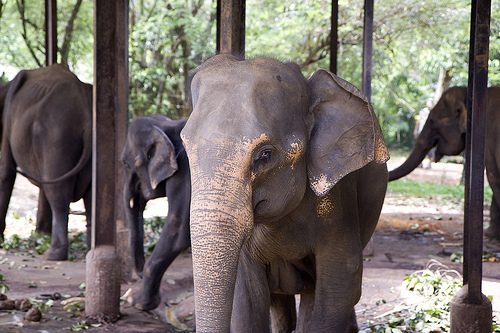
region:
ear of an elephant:
[338, 109, 399, 173]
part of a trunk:
[201, 272, 234, 312]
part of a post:
[448, 215, 488, 297]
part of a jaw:
[261, 176, 300, 231]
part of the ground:
[41, 278, 81, 313]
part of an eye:
[252, 147, 284, 154]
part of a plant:
[410, 269, 442, 312]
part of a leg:
[315, 242, 352, 309]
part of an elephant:
[119, 177, 322, 242]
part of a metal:
[459, 260, 486, 310]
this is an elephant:
[178, 48, 375, 301]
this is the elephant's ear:
[309, 72, 386, 188]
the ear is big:
[318, 63, 386, 192]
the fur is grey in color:
[227, 71, 289, 111]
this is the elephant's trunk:
[190, 165, 252, 323]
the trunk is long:
[191, 239, 232, 326]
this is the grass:
[397, 249, 444, 330]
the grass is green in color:
[411, 265, 448, 321]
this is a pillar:
[462, 12, 485, 182]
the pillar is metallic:
[463, 178, 478, 243]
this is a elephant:
[186, 32, 368, 332]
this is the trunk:
[188, 226, 231, 331]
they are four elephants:
[6, 64, 498, 232]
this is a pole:
[459, 11, 498, 299]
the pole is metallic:
[468, 121, 481, 174]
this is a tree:
[136, 6, 203, 55]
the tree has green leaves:
[381, 96, 402, 121]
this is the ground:
[9, 271, 65, 316]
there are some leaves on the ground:
[416, 268, 437, 311]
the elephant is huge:
[193, 58, 380, 313]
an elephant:
[157, 43, 432, 303]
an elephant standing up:
[96, 20, 433, 331]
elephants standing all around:
[12, 27, 499, 256]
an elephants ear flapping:
[276, 52, 435, 227]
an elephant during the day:
[104, 13, 467, 330]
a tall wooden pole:
[47, 1, 164, 321]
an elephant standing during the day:
[129, 22, 428, 331]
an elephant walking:
[94, 43, 236, 306]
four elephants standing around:
[12, 35, 497, 306]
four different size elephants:
[4, 8, 499, 297]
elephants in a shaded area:
[5, 6, 490, 328]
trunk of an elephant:
[175, 156, 258, 328]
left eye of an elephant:
[248, 135, 282, 173]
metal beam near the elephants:
[452, 0, 494, 332]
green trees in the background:
[382, 7, 457, 74]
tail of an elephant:
[19, 115, 92, 203]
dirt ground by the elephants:
[371, 235, 418, 288]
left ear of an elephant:
[139, 128, 187, 190]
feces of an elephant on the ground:
[2, 287, 45, 327]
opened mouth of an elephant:
[425, 137, 445, 167]